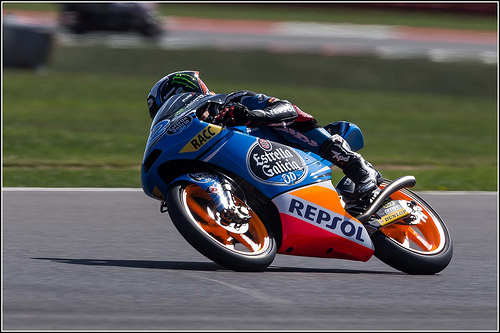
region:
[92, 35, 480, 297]
the person is leaning left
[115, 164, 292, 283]
the wheel is black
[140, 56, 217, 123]
the person is wearing a helmet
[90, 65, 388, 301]
the bike is mainly blue with a little orange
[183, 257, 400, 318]
the road is grey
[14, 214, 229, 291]
shadow on the ground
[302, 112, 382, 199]
the person is wearing boots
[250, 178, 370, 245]
the writing is blue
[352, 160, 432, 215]
the pipe is silver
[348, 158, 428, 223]
the pipe is made of metal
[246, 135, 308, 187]
advertisement for estrella galicia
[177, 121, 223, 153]
advertisement for RACC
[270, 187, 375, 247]
advertisement on motorcycle for REPSOL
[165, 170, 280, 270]
black and orange wheel on front of bike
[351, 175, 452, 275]
black and orange wheel on back of bike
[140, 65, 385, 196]
man riding on a motorcycle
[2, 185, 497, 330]
road to race motorcycles on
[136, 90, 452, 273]
blue racing motorcycle in action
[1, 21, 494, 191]
green field behind race track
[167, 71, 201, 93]
advertisement on helmet for monster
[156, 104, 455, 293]
a motorcycle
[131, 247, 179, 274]
the shadow on the road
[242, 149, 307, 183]
logo ont the motorcycle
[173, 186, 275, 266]
front wheel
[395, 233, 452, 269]
back wheel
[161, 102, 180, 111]
shield of the motorcycle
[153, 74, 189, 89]
person is wearing a helmet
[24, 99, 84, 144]
a field of green grass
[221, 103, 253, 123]
person is wearing gloves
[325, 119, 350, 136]
seat of the motorcycle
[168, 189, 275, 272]
front Tyre of the bike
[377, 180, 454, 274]
back Tyre of the bike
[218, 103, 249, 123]
man wearing gloves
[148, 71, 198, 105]
man wearing printed helmet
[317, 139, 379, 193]
man wearing black color shoes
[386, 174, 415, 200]
silencer pipe of the bike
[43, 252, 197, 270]
shadow of bike falling on ground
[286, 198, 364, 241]
REPSOL mentioned on body of bike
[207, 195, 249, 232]
front disc brake of bike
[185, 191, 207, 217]
orange color spoke of bike wheel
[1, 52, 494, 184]
green grass on ground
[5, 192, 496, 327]
paved surface of track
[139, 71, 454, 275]
rider on tilted motorbike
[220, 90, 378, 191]
uniform on cempetitive racer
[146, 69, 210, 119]
bike helmet on head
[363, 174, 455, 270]
orange spokes in wheel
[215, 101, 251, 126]
gloved hand on handle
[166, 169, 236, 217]
fender over bike tire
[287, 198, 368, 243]
black word on white